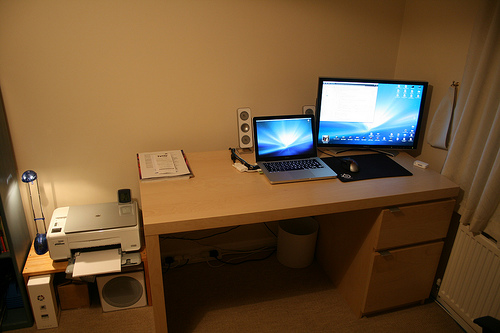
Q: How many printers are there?
A: One.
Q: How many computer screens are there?
A: Two.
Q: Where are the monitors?
A: On the desk.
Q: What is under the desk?
A: Trash Can.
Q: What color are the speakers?
A: White.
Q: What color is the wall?
A: Beige.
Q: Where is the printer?
A: To the left of the desk.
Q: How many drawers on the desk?
A: Two.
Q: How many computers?
A: Two.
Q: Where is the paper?
A: In printer.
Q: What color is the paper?
A: White.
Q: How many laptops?
A: One.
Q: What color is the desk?
A: Brown.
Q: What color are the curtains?
A: White.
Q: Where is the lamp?
A: Next to printer.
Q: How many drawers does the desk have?
A: Two.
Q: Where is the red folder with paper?
A: On desk.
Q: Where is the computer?
A: On the desk.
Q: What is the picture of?
A: Computer desk.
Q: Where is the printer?
A: Shelf.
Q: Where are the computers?
A: Computer desk.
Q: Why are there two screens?
A: Laptop external display.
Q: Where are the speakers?
A: Behind laptop.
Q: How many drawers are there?
A: 2.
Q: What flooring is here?
A: Carpet.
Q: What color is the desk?
A: Brown.